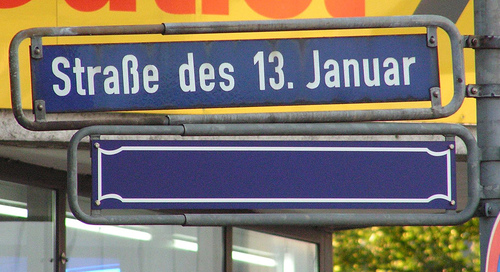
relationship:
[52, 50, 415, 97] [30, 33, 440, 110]
text on sign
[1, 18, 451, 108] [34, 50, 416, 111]
sign for road written in spanish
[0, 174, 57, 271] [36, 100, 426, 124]
glass windows behind a road sign written in spanish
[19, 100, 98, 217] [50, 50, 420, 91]
road sign written in spanish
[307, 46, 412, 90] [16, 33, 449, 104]
letters on sign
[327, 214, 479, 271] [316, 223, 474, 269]
leaves in background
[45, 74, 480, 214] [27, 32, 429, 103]
two different sign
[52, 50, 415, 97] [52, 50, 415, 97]
text in text